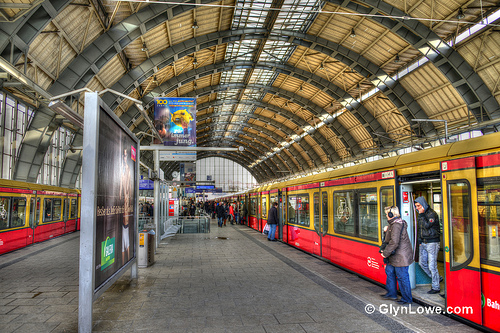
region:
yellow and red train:
[220, 132, 495, 329]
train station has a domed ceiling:
[3, 3, 498, 169]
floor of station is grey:
[168, 241, 262, 331]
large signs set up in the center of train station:
[76, 96, 181, 316]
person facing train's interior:
[257, 189, 293, 248]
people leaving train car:
[371, 183, 455, 313]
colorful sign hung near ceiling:
[138, 80, 214, 172]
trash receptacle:
[131, 218, 161, 270]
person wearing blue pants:
[377, 260, 416, 302]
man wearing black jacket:
[415, 208, 442, 246]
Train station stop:
[15, 14, 498, 320]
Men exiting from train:
[329, 138, 498, 291]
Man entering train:
[242, 187, 313, 258]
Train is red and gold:
[227, 136, 484, 290]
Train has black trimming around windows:
[270, 168, 494, 291]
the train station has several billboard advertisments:
[37, 84, 221, 325]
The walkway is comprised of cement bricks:
[178, 232, 332, 332]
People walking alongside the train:
[170, 182, 262, 245]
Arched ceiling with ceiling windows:
[7, 6, 488, 200]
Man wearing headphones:
[362, 198, 419, 306]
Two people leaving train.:
[381, 191, 447, 303]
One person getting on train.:
[256, 198, 286, 248]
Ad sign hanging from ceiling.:
[152, 88, 203, 165]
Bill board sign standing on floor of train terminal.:
[75, 89, 150, 330]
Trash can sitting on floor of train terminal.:
[136, 224, 164, 273]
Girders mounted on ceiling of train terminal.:
[198, 9, 490, 145]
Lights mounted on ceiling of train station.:
[325, 69, 418, 111]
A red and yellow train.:
[284, 136, 496, 332]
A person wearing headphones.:
[384, 201, 401, 220]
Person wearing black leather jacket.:
[413, 203, 440, 243]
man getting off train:
[412, 195, 443, 295]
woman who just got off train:
[379, 204, 417, 306]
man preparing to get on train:
[258, 199, 282, 244]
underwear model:
[115, 142, 134, 267]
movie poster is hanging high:
[153, 92, 199, 162]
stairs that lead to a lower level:
[176, 212, 215, 239]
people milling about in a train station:
[212, 195, 248, 232]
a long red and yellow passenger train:
[222, 130, 499, 325]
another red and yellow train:
[1, 176, 85, 253]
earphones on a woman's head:
[382, 203, 404, 222]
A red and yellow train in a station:
[218, 123, 498, 328]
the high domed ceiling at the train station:
[6, 7, 497, 147]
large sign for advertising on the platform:
[42, 84, 154, 325]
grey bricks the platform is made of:
[166, 246, 319, 326]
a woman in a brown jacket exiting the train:
[371, 200, 416, 305]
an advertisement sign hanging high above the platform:
[151, 87, 198, 156]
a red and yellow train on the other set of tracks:
[4, 173, 84, 258]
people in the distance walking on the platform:
[204, 193, 237, 228]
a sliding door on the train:
[435, 161, 487, 323]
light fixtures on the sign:
[38, 87, 151, 119]